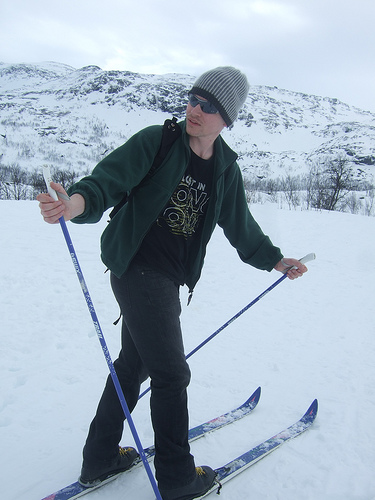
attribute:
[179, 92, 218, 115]
sunglasses. — dark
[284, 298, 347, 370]
snow — abundant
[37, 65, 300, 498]
skier — cross country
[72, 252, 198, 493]
pants — black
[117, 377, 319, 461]
skis — red, blue, white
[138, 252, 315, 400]
ski pole — skinny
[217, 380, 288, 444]
ski — blue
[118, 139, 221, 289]
tshirt — black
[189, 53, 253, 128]
cap — knit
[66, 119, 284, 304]
jacket — small, green 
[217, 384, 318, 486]
ski — yellow 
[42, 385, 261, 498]
ski — blue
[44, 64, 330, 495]
skier — cross country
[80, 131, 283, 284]
jacket — man's, green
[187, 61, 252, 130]
cap — stocking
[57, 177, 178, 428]
pole — blue, white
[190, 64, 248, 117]
hat — black, grey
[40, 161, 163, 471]
pole — skinny, blue